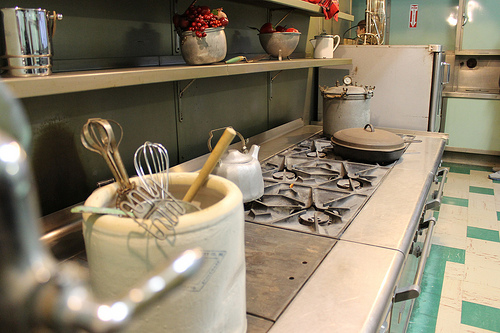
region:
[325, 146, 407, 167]
a cat iron pan on a stove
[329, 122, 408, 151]
a lid on a cast iron pot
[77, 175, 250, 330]
a crock on a counter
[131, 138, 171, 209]
a wisk in a crock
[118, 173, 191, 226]
a potato masher in a crock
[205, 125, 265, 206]
a tea kettle on a stove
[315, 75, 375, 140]
a pressure cooker on a stove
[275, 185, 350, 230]
a gas burner on a stove top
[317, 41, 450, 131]
an old white refrigerator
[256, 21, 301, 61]
a metal colander full of apples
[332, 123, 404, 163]
A cast iron pan on a stove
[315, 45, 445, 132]
An old, white kitchen refrigerator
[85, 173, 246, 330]
A ceramic jar containing various kitchen utensils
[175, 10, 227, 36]
A cluster of red berries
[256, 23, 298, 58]
A bowl full of red apples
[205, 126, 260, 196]
A silver, aluminum tea kettle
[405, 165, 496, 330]
Green and white floor tiles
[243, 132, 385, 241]
Old, iron burners on a stove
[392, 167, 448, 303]
Handles to open kitchen ovens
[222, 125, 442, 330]
A dirty kitchen counter and stove top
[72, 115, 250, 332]
Ktichen utensils in white crock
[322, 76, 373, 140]
Pressure cooker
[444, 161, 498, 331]
Green and white tile floor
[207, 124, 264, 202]
White tea pot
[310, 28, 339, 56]
White coffee pot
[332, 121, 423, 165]
Black skillet with brown lid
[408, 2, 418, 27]
Sign pointing to fire extinguisher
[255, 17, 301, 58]
Colander with red fruit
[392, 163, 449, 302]
Metal oven door handles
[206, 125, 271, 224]
the kettle is gray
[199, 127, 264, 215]
the kettle is gray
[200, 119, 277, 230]
the kettle is gray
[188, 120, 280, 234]
the kettle is gray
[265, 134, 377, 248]
dust on the stove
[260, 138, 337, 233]
dust on the stove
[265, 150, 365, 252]
dust on the stove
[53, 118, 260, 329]
this is a jar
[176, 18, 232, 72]
this is a pot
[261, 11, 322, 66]
this is a pot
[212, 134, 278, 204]
this is a kettle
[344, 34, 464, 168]
this is a fridge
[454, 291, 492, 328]
this is a tile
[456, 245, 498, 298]
this is a tile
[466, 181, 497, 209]
this is a tile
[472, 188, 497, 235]
this is a tile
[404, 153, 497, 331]
green and tan checkered kitchen floor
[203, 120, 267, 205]
white tea kettle on stove top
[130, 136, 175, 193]
A silver whisk.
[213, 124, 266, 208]
A silver teakettle on the stove.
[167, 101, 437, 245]
A large stovetop.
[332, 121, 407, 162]
A black frying pan.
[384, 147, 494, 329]
Green and white tiles on the floor.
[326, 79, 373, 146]
A large grey pot with a lid.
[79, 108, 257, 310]
Kitchen utensils in a tall white bowl.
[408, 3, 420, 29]
A red and white sign on the wall.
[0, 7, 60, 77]
a metal container on the shelf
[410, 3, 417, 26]
an arrow pointing down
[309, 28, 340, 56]
a white pitcher on the shelf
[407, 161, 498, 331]
a green and cream floor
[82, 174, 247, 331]
container with utensils